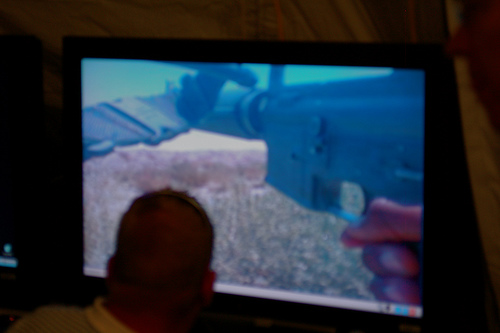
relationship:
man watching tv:
[4, 186, 216, 331] [60, 34, 445, 332]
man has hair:
[4, 186, 216, 331] [116, 189, 212, 318]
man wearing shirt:
[4, 186, 216, 331] [4, 295, 133, 332]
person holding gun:
[342, 197, 422, 306] [237, 70, 423, 222]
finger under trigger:
[339, 221, 365, 249] [360, 185, 370, 215]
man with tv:
[4, 186, 216, 331] [60, 34, 445, 332]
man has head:
[4, 186, 216, 331] [106, 193, 216, 332]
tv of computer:
[60, 34, 445, 332] [1, 232, 46, 280]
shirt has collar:
[4, 295, 133, 332] [86, 297, 133, 332]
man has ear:
[4, 186, 216, 331] [201, 268, 215, 304]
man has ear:
[4, 186, 216, 331] [201, 268, 221, 304]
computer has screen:
[1, 232, 46, 280] [60, 34, 445, 332]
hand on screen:
[342, 197, 421, 303] [60, 34, 445, 332]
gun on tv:
[237, 70, 423, 222] [60, 34, 445, 332]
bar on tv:
[84, 266, 423, 316] [60, 34, 445, 332]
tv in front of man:
[60, 34, 445, 332] [4, 186, 216, 331]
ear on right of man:
[201, 268, 215, 304] [4, 186, 216, 331]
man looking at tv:
[4, 186, 216, 331] [60, 34, 445, 332]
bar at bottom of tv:
[84, 266, 423, 316] [60, 34, 445, 332]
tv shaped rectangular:
[60, 34, 445, 332] [65, 36, 436, 332]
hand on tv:
[342, 197, 421, 303] [60, 34, 445, 332]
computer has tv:
[1, 232, 46, 280] [60, 34, 445, 332]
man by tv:
[4, 186, 216, 331] [60, 34, 445, 332]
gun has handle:
[237, 70, 423, 222] [366, 179, 426, 282]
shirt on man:
[4, 295, 133, 332] [4, 186, 216, 331]